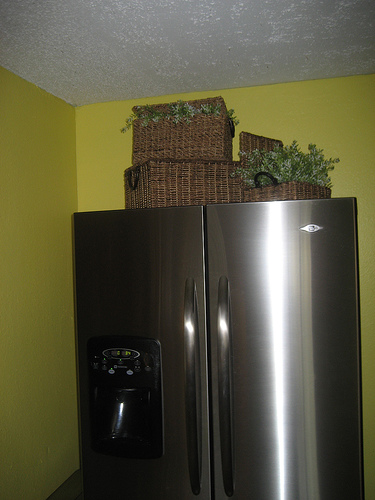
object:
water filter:
[85, 342, 167, 423]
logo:
[300, 223, 323, 233]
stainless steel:
[221, 236, 339, 424]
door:
[204, 197, 365, 499]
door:
[74, 205, 213, 500]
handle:
[127, 166, 140, 190]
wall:
[0, 0, 375, 108]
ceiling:
[2, 1, 373, 106]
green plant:
[233, 140, 342, 185]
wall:
[0, 65, 79, 498]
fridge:
[73, 197, 367, 499]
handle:
[216, 274, 236, 498]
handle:
[181, 277, 202, 496]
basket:
[242, 171, 331, 204]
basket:
[131, 95, 235, 164]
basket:
[123, 156, 242, 209]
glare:
[264, 198, 293, 498]